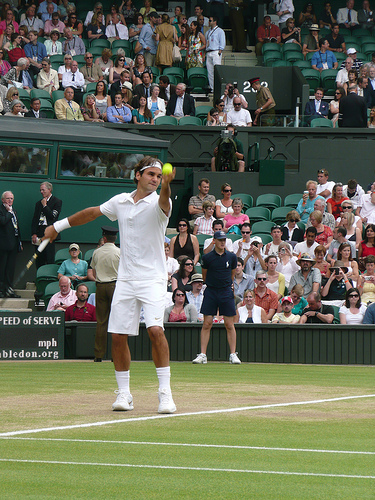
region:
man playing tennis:
[23, 154, 175, 413]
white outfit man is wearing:
[97, 187, 173, 333]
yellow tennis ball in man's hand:
[158, 160, 173, 171]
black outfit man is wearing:
[197, 246, 237, 315]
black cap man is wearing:
[211, 228, 227, 238]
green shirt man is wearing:
[56, 257, 88, 279]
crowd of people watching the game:
[0, 0, 373, 324]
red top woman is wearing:
[327, 192, 349, 216]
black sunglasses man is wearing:
[238, 228, 255, 234]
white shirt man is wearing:
[229, 106, 250, 126]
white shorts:
[117, 288, 136, 327]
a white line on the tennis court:
[175, 438, 218, 454]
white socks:
[156, 369, 171, 388]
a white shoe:
[156, 396, 177, 413]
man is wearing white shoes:
[192, 350, 205, 363]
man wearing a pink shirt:
[49, 291, 64, 302]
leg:
[225, 321, 239, 349]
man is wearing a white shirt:
[119, 224, 150, 273]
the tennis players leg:
[152, 333, 172, 366]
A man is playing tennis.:
[0, 154, 181, 424]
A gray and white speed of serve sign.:
[0, 310, 63, 356]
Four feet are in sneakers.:
[111, 351, 241, 412]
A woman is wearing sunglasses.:
[340, 289, 368, 324]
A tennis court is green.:
[0, 362, 374, 498]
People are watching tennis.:
[2, 0, 373, 322]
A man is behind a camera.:
[212, 124, 247, 173]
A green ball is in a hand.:
[160, 161, 175, 185]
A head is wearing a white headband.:
[133, 156, 163, 188]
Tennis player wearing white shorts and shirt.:
[42, 153, 200, 428]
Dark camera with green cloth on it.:
[217, 127, 235, 171]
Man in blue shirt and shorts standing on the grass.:
[189, 226, 241, 371]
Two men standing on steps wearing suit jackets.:
[2, 179, 55, 297]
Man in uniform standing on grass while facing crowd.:
[90, 221, 121, 365]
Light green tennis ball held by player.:
[161, 159, 173, 176]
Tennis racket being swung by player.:
[0, 235, 52, 301]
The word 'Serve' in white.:
[33, 314, 60, 324]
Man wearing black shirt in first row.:
[301, 287, 334, 326]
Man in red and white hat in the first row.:
[270, 294, 300, 322]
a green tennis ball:
[160, 162, 175, 173]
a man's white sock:
[153, 365, 171, 390]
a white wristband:
[52, 218, 71, 232]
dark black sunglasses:
[347, 292, 358, 300]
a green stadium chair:
[254, 194, 282, 209]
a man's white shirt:
[99, 188, 173, 283]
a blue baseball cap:
[213, 231, 229, 241]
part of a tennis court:
[3, 362, 373, 497]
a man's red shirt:
[65, 300, 96, 320]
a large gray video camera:
[217, 130, 233, 151]